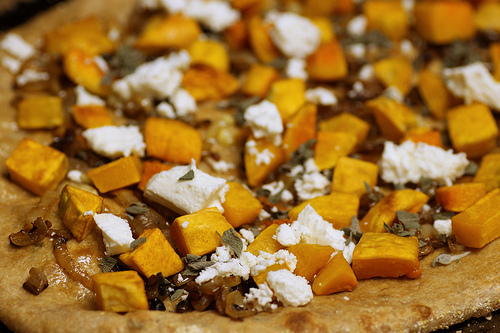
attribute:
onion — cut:
[47, 228, 117, 307]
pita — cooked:
[3, 3, 499, 332]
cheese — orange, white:
[312, 252, 362, 301]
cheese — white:
[378, 137, 468, 187]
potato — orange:
[126, 225, 185, 277]